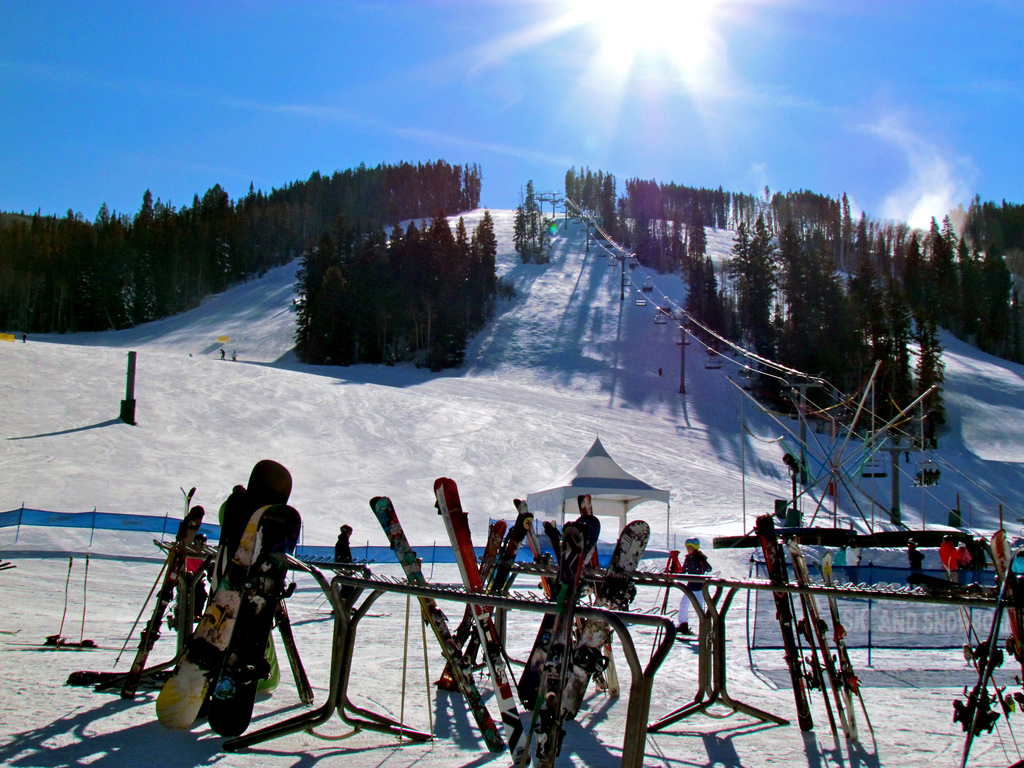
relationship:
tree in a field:
[302, 185, 457, 325] [344, 222, 530, 378]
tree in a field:
[302, 232, 334, 372] [143, 323, 682, 678]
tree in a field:
[512, 178, 552, 261] [461, 254, 674, 435]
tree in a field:
[289, 229, 382, 346] [60, 249, 917, 629]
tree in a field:
[515, 209, 532, 267] [2, 156, 1023, 458]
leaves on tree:
[388, 240, 433, 285] [6, 158, 503, 367]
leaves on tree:
[885, 326, 904, 349] [768, 219, 925, 436]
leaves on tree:
[742, 265, 926, 400] [798, 226, 844, 433]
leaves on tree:
[854, 212, 1023, 353] [981, 240, 1008, 359]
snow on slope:
[2, 197, 1006, 766] [2, 192, 1020, 673]